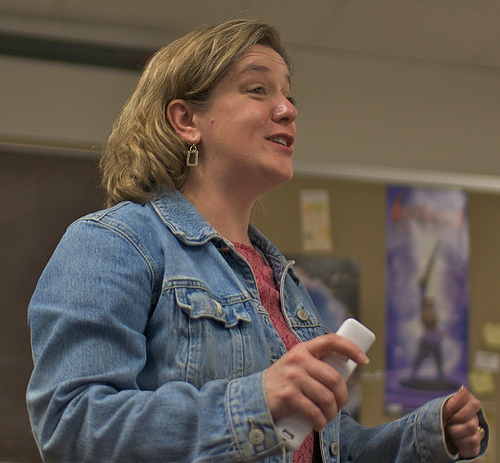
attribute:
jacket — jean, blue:
[49, 170, 274, 437]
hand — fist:
[263, 339, 343, 422]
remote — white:
[321, 325, 380, 371]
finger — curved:
[446, 386, 485, 428]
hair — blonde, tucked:
[80, 115, 151, 168]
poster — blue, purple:
[387, 179, 462, 399]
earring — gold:
[186, 144, 201, 168]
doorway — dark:
[4, 143, 94, 219]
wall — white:
[365, 60, 457, 149]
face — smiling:
[209, 40, 307, 185]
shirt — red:
[239, 239, 278, 282]